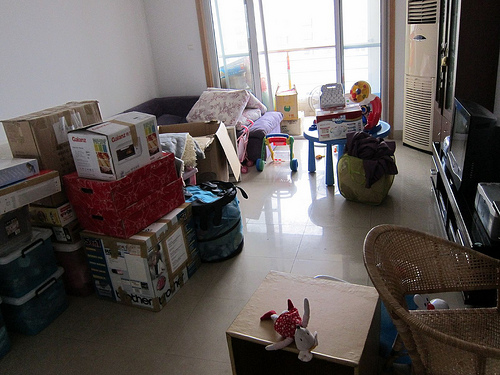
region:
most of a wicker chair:
[363, 222, 498, 369]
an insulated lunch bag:
[318, 81, 345, 109]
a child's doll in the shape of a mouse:
[260, 297, 320, 362]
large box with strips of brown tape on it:
[81, 200, 199, 312]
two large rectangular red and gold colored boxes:
[64, 152, 186, 239]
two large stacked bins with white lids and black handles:
[0, 227, 68, 339]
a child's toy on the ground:
[255, 132, 300, 172]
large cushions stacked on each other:
[186, 86, 266, 128]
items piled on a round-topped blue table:
[303, 80, 391, 186]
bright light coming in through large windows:
[203, 0, 387, 137]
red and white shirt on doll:
[286, 315, 296, 325]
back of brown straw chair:
[391, 248, 416, 270]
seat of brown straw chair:
[453, 321, 480, 335]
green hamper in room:
[346, 174, 361, 197]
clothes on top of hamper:
[363, 138, 383, 155]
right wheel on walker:
[284, 156, 300, 176]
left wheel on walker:
[254, 157, 266, 173]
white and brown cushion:
[206, 91, 230, 110]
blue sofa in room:
[153, 102, 170, 112]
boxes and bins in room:
[18, 131, 163, 331]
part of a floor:
[339, 242, 373, 272]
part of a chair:
[416, 268, 425, 288]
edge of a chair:
[384, 278, 389, 293]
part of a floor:
[85, 303, 100, 317]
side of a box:
[105, 230, 180, 332]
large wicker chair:
[358, 215, 490, 363]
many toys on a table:
[300, 83, 390, 124]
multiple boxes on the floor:
[20, 101, 190, 314]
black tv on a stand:
[439, 97, 484, 184]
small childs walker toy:
[260, 130, 302, 167]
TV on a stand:
[445, 99, 497, 189]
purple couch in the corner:
[124, 93, 238, 139]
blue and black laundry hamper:
[190, 180, 266, 258]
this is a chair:
[358, 213, 498, 373]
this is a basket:
[166, 174, 266, 272]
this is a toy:
[256, 296, 331, 369]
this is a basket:
[65, 110, 165, 187]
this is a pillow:
[171, 83, 267, 143]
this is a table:
[286, 105, 398, 201]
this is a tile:
[302, 190, 375, 240]